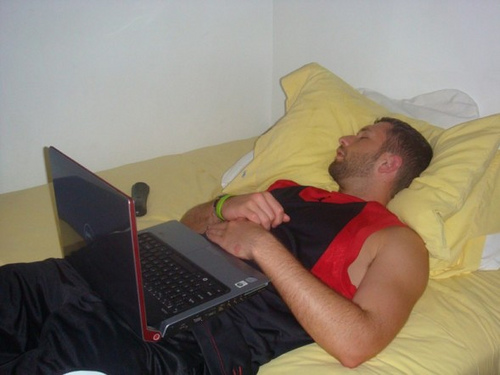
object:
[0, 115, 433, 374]
man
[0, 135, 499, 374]
bed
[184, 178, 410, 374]
shirt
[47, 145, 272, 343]
laptop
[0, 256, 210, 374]
pants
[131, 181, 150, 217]
control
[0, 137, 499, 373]
sheet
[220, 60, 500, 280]
pillowcase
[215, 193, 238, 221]
bracelet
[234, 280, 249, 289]
sticker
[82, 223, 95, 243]
logo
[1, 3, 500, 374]
bedroom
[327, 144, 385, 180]
beard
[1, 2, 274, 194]
wall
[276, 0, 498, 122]
wall